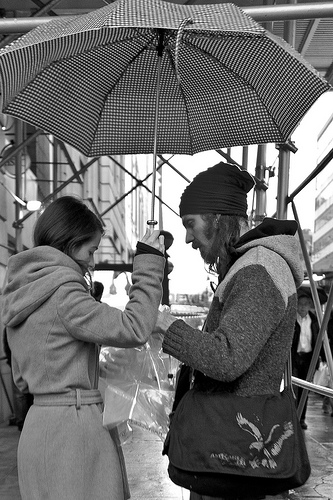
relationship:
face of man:
[181, 205, 211, 268] [171, 169, 297, 498]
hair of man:
[205, 210, 266, 271] [171, 169, 297, 498]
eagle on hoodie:
[233, 406, 289, 475] [160, 217, 304, 400]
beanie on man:
[179, 159, 257, 217] [171, 169, 297, 498]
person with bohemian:
[0, 197, 166, 500] [171, 169, 297, 498]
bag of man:
[163, 348, 312, 494] [171, 169, 297, 498]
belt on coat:
[28, 390, 104, 409] [9, 253, 116, 499]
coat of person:
[9, 253, 116, 499] [0, 197, 166, 500]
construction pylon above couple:
[0, 0, 333, 424] [0, 160, 313, 500]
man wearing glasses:
[293, 298, 317, 360] [298, 301, 312, 308]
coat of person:
[0, 245, 167, 499] [0, 197, 166, 500]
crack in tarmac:
[313, 473, 330, 496] [12, 414, 324, 499]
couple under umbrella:
[15, 180, 313, 458] [8, 3, 296, 145]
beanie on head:
[179, 159, 257, 217] [178, 159, 247, 252]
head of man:
[178, 159, 247, 252] [171, 169, 297, 498]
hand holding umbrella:
[141, 232, 160, 256] [8, 3, 296, 145]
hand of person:
[141, 232, 160, 256] [0, 197, 166, 500]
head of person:
[37, 198, 122, 273] [0, 197, 166, 500]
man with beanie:
[171, 169, 297, 498] [179, 159, 257, 217]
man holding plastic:
[171, 169, 297, 498] [99, 320, 187, 425]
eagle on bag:
[235, 410, 294, 471] [163, 348, 312, 494]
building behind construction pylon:
[98, 151, 156, 261] [16, 97, 282, 271]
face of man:
[299, 303, 314, 318] [290, 294, 317, 431]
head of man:
[178, 159, 247, 252] [152, 160, 305, 500]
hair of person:
[46, 199, 89, 242] [0, 197, 166, 500]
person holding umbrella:
[19, 200, 139, 485] [8, 3, 296, 145]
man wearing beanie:
[152, 160, 305, 500] [179, 159, 257, 217]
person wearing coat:
[0, 197, 166, 500] [9, 253, 116, 499]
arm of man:
[166, 312, 282, 385] [152, 160, 305, 500]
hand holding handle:
[141, 232, 160, 256] [147, 219, 157, 271]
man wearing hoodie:
[152, 160, 305, 500] [214, 238, 306, 393]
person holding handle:
[0, 197, 166, 500] [147, 219, 157, 271]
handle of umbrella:
[147, 219, 157, 271] [8, 3, 296, 145]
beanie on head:
[185, 164, 248, 212] [178, 159, 247, 252]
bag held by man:
[163, 348, 312, 494] [171, 169, 297, 498]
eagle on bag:
[233, 406, 289, 475] [163, 348, 312, 494]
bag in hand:
[112, 339, 168, 432] [141, 232, 160, 256]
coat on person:
[9, 253, 116, 499] [0, 197, 166, 500]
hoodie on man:
[160, 217, 304, 400] [171, 169, 297, 498]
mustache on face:
[187, 242, 202, 250] [181, 205, 211, 268]